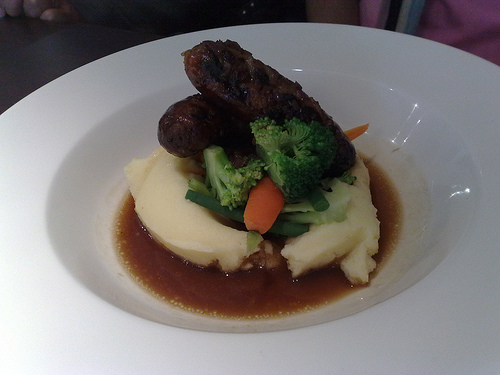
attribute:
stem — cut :
[204, 146, 231, 183]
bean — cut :
[305, 186, 328, 211]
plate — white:
[409, 63, 457, 124]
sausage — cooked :
[178, 35, 263, 95]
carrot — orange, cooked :
[255, 199, 276, 220]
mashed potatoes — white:
[343, 205, 366, 229]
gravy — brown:
[224, 277, 281, 304]